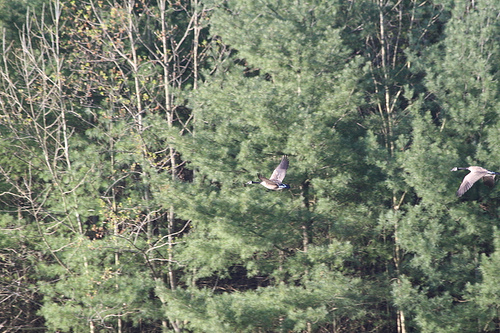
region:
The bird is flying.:
[223, 139, 320, 210]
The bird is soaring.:
[238, 136, 300, 216]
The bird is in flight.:
[243, 104, 305, 219]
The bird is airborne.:
[241, 137, 306, 202]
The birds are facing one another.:
[236, 147, 498, 213]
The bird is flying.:
[451, 157, 499, 196]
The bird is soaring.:
[429, 148, 498, 200]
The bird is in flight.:
[446, 152, 498, 205]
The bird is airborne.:
[432, 130, 498, 227]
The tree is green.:
[138, 0, 415, 330]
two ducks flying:
[219, 139, 491, 219]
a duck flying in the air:
[220, 141, 322, 221]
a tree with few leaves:
[57, 15, 204, 185]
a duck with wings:
[231, 139, 309, 221]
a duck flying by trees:
[426, 152, 496, 222]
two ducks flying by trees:
[227, 147, 490, 227]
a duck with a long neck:
[241, 155, 308, 223]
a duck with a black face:
[220, 145, 291, 215]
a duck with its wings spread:
[232, 152, 295, 217]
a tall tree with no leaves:
[362, 4, 419, 182]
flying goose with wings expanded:
[439, 155, 497, 210]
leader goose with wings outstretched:
[241, 147, 297, 199]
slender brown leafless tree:
[11, 7, 93, 194]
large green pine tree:
[213, 14, 373, 324]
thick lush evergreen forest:
[15, 9, 433, 315]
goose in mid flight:
[242, 154, 308, 210]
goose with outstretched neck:
[438, 155, 496, 213]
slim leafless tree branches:
[355, 7, 424, 135]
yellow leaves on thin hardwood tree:
[63, 6, 165, 194]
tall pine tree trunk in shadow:
[295, 175, 329, 272]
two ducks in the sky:
[248, 160, 490, 200]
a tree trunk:
[293, 213, 318, 254]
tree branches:
[30, 115, 75, 190]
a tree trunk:
[385, 310, 410, 325]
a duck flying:
[230, 165, 305, 198]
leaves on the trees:
[60, 55, 115, 92]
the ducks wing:
[456, 175, 486, 198]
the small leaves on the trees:
[98, 208, 140, 230]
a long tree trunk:
[158, 146, 179, 176]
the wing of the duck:
[270, 161, 300, 176]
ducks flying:
[445, 159, 497, 202]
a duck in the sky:
[243, 166, 309, 203]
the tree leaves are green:
[197, 184, 274, 253]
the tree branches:
[27, 96, 69, 148]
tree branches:
[392, 304, 410, 331]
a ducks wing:
[450, 170, 479, 198]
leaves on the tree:
[67, 71, 119, 95]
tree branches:
[4, 291, 37, 331]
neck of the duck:
[251, 179, 261, 188]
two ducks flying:
[244, 155, 497, 200]